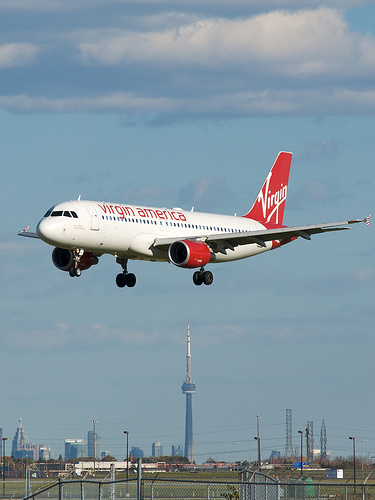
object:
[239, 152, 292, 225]
tail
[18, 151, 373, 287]
airplane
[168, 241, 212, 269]
engine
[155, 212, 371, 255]
wing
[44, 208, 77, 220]
windshield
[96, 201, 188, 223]
writing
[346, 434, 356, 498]
light pole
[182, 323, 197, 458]
tower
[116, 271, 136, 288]
wheel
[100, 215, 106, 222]
window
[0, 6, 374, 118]
clouds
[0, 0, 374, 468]
sky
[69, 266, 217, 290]
wheels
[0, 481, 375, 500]
metal fence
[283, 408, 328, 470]
metal structures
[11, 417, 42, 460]
building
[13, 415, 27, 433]
roof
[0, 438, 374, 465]
airport